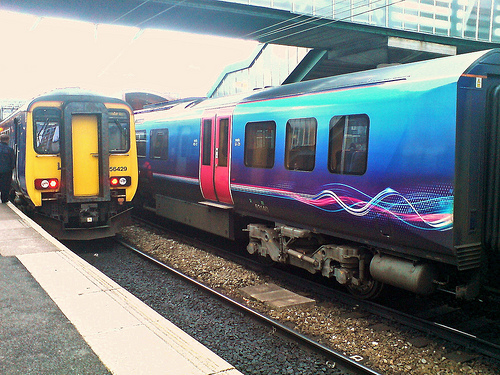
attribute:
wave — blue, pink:
[215, 158, 479, 246]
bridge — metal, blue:
[54, 19, 459, 68]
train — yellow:
[12, 96, 137, 204]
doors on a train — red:
[195, 111, 237, 217]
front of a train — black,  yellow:
[25, 88, 142, 218]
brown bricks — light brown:
[58, 229, 281, 364]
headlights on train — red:
[29, 169, 71, 198]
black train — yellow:
[21, 78, 149, 234]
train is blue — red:
[170, 90, 499, 295]